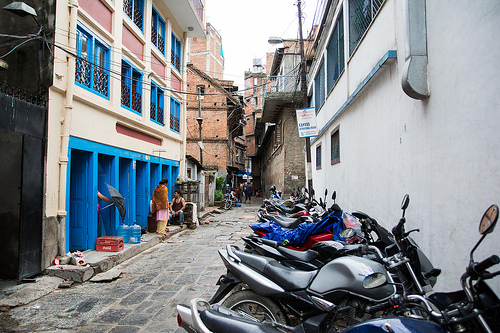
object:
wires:
[38, 3, 327, 97]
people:
[236, 181, 244, 202]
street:
[84, 282, 162, 330]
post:
[190, 76, 235, 209]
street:
[157, 225, 259, 260]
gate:
[0, 84, 47, 290]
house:
[252, 32, 304, 203]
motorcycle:
[257, 188, 329, 219]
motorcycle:
[256, 189, 330, 229]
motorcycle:
[248, 190, 365, 250]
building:
[293, 0, 499, 291]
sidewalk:
[421, 125, 465, 221]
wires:
[0, 36, 41, 60]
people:
[243, 182, 253, 204]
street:
[227, 196, 263, 219]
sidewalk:
[43, 215, 60, 267]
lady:
[97, 187, 115, 229]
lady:
[150, 178, 170, 235]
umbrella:
[101, 180, 127, 223]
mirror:
[398, 193, 414, 209]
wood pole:
[294, 0, 314, 202]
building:
[186, 61, 245, 203]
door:
[66, 147, 96, 257]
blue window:
[93, 37, 112, 100]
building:
[186, 0, 228, 82]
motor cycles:
[257, 187, 328, 228]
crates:
[93, 235, 126, 253]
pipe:
[55, 72, 79, 256]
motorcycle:
[206, 196, 440, 322]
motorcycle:
[175, 203, 499, 327]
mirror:
[471, 200, 498, 234]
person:
[235, 188, 242, 201]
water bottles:
[115, 219, 128, 243]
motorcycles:
[262, 187, 316, 215]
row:
[174, 177, 499, 331]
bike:
[241, 208, 393, 270]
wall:
[344, 124, 391, 188]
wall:
[84, 0, 115, 26]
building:
[0, 0, 199, 305]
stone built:
[260, 104, 295, 193]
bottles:
[129, 220, 142, 244]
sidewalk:
[76, 115, 115, 133]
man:
[168, 189, 187, 227]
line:
[173, 183, 497, 332]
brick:
[45, 264, 96, 284]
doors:
[94, 153, 123, 253]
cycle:
[218, 191, 234, 210]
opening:
[242, 177, 253, 196]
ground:
[5, 318, 30, 329]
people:
[255, 187, 263, 198]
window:
[72, 29, 93, 91]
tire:
[218, 289, 287, 329]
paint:
[296, 108, 317, 138]